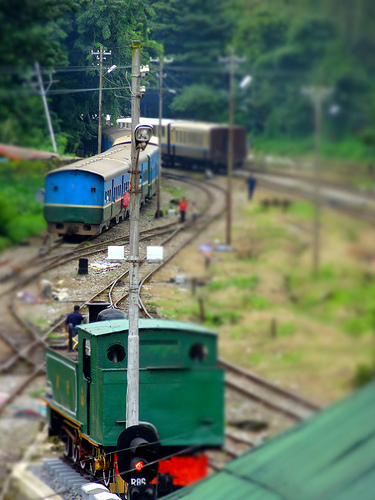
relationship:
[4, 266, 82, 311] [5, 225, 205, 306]
trash on tracks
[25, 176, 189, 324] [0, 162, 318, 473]
gravel between tracks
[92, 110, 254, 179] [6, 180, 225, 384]
train on tracks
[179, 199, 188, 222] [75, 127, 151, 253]
figurine standing between trains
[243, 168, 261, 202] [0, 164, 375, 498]
person on railway crossway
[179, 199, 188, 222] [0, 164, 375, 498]
figurine on railway crossway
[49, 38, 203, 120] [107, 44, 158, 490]
wires on pole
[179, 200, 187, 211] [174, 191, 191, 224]
red shirt on person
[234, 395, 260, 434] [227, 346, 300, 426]
trees by tracks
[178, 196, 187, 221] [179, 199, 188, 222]
figurine of a figurine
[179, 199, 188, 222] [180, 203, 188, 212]
figurine wearing a red shirt